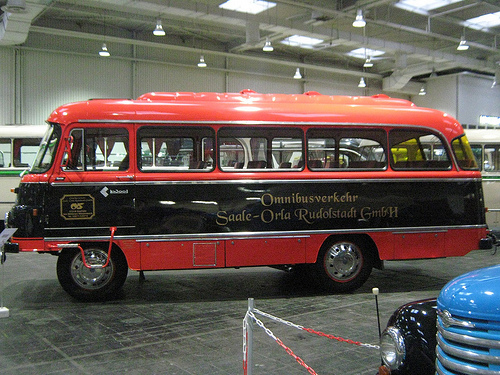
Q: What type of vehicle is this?
A: Bus.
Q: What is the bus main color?
A: Red.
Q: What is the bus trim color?
A: Black.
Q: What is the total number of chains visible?
A: 3.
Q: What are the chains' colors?
A: Red and white.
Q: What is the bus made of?
A: Metal.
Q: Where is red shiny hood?
A: On mini bus.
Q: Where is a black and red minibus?
A: It is parked in a garage.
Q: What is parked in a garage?
A: Red tour bus with black stripe.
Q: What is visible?
A: The bus.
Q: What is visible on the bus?
A: The letters.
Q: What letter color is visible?
A: Gold.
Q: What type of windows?
A: Square windows.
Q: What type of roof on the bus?
A: Raised roof.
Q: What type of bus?
A: Transit bus.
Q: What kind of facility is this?
A: Garage.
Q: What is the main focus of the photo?
A: Bus.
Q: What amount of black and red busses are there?
A: 1.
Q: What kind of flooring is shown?
A: Cement.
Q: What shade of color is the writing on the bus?
A: Gold.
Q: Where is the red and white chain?
A: Next to the blue and black vehicle.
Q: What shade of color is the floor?
A: Dark gray.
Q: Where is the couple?
A: There are no people.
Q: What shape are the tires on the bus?
A: Round.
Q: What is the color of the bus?
A: Red.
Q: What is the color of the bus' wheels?
A: Black.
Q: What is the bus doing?
A: Nothing.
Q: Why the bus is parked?
A: For display.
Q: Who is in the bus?
A: No one.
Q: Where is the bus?
A: In a garage.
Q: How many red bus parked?
A: One.